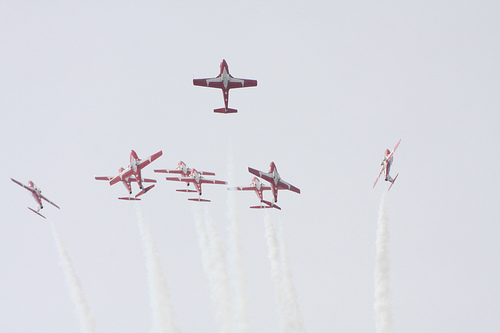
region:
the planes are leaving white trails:
[23, 112, 398, 331]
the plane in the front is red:
[190, 57, 265, 123]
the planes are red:
[8, 56, 403, 228]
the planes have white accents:
[8, 56, 410, 237]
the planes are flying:
[6, 50, 416, 230]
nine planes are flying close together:
[1, 52, 416, 239]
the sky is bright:
[0, 0, 499, 332]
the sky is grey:
[0, 1, 499, 331]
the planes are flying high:
[9, 55, 406, 222]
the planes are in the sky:
[5, 49, 410, 232]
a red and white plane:
[173, 56, 275, 138]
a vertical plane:
[168, 56, 274, 126]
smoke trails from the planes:
[13, 215, 452, 329]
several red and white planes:
[2, 55, 441, 235]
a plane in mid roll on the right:
[346, 125, 451, 231]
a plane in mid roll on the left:
[7, 166, 86, 236]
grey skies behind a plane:
[0, 14, 483, 117]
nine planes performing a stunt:
[0, 51, 450, 278]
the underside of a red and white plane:
[184, 51, 274, 141]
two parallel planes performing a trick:
[152, 148, 237, 226]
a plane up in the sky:
[186, 50, 260, 122]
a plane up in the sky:
[371, 135, 408, 189]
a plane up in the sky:
[248, 158, 301, 207]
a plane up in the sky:
[229, 173, 280, 217]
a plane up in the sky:
[171, 166, 224, 213]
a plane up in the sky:
[157, 161, 212, 199]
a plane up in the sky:
[115, 148, 172, 214]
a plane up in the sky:
[96, 160, 162, 209]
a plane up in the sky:
[12, 172, 59, 222]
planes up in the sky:
[6, 41, 404, 240]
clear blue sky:
[288, 30, 425, 101]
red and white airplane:
[187, 41, 268, 121]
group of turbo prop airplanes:
[13, 42, 444, 228]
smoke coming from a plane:
[364, 163, 434, 312]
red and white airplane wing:
[233, 64, 277, 96]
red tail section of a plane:
[202, 93, 259, 120]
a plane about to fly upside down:
[10, 155, 65, 240]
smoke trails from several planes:
[41, 183, 426, 307]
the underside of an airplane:
[98, 45, 360, 145]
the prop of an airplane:
[209, 45, 247, 74]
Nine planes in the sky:
[8, 55, 425, 207]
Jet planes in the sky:
[3, 46, 446, 220]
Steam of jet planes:
[45, 195, 406, 326]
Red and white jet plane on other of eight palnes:
[183, 53, 269, 120]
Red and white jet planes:
[7, 53, 417, 223]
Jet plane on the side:
[360, 132, 406, 194]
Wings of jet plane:
[187, 71, 260, 88]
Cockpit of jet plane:
[215, 53, 232, 71]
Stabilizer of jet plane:
[211, 105, 238, 113]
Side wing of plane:
[230, 75, 259, 92]